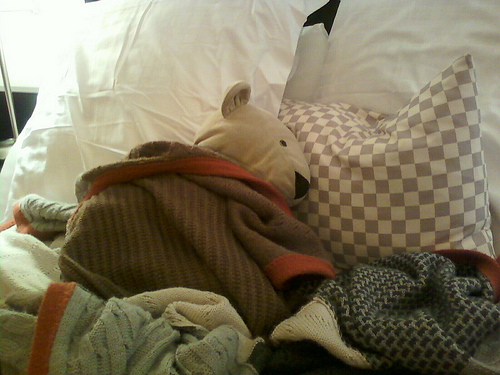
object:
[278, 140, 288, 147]
black eye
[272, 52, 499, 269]
pillow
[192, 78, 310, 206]
bear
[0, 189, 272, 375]
blanket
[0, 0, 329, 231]
pillow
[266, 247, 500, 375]
blanket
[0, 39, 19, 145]
bar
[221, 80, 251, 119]
ear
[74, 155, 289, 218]
border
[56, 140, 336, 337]
blanket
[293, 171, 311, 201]
nose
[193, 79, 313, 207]
head